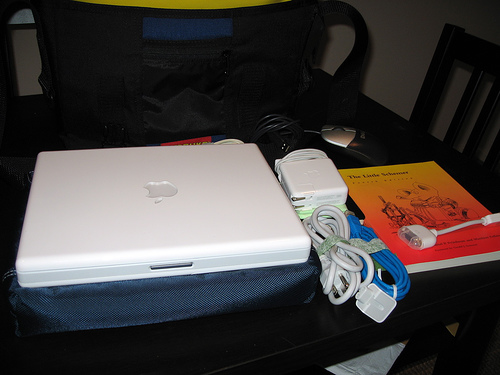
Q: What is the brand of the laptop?
A: Apple.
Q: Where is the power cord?
A: On the left of the laptop.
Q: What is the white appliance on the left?
A: Laptop.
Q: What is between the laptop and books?
A: Cords.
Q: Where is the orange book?
A: Right of laptop.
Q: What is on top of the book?
A: Laptop cord.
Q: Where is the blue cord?
A: Right of laptop.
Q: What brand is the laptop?
A: Mac.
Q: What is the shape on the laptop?
A: Apple.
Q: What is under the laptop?
A: Laptop case.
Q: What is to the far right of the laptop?
A: Book.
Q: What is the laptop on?
A: Table.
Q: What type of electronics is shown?
A: Laptop.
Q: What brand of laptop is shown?
A: Apple.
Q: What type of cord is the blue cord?
A: Ethernet.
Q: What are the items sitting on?
A: Table.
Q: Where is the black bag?
A: Behind the laptop.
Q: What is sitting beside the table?
A: Chairs.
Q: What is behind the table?
A: Wall.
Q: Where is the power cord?
A: Beside the laptop.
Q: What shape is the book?
A: Rectangle.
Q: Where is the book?
A: Beside the power cord.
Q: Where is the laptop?
A: On a black table.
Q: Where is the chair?
A: On the right from the table.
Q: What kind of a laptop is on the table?
A: A mac.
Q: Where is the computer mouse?
A: Next to the orange book.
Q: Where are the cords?
A: Between the laptop and the book.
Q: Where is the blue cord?
A: Next to the white one.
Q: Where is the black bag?
A: Behind the laptop computer.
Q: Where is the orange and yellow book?
A: On the right from the cords.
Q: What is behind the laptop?
A: A black bag.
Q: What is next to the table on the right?
A: A chair.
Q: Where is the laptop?
A: ON the table.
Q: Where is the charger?
A: Next to the laptop.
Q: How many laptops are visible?
A: One.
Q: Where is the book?
A: In front of the power cords.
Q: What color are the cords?
A: Blue and white.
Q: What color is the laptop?
A: White.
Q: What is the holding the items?
A: A large table.